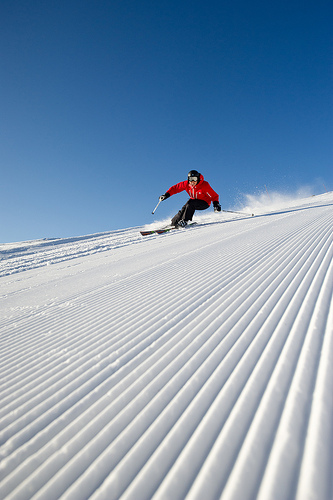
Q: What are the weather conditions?
A: It is cloudless.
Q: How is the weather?
A: It is cloudless.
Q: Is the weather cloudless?
A: Yes, it is cloudless.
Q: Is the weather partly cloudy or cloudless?
A: It is cloudless.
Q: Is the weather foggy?
A: No, it is cloudless.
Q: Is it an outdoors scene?
A: Yes, it is outdoors.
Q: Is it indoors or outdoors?
A: It is outdoors.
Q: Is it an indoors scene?
A: No, it is outdoors.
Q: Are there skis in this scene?
A: Yes, there are skis.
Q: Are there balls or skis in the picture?
A: Yes, there are skis.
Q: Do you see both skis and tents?
A: No, there are skis but no tents.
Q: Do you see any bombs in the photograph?
A: No, there are no bombs.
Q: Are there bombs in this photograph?
A: No, there are no bombs.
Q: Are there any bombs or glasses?
A: No, there are no bombs or glasses.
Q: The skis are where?
A: The skis are on the snow.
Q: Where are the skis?
A: The skis are on the snow.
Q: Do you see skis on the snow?
A: Yes, there are skis on the snow.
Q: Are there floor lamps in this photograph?
A: No, there are no floor lamps.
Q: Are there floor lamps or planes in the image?
A: No, there are no floor lamps or planes.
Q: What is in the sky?
A: The clouds are in the sky.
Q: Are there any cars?
A: No, there are no cars.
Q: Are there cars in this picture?
A: No, there are no cars.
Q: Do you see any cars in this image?
A: No, there are no cars.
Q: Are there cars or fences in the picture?
A: No, there are no cars or fences.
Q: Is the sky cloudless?
A: Yes, the sky is cloudless.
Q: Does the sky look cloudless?
A: Yes, the sky is cloudless.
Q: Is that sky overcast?
A: No, the sky is cloudless.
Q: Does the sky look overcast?
A: No, the sky is cloudless.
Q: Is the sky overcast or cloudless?
A: The sky is cloudless.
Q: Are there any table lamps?
A: No, there are no table lamps.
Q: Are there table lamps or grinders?
A: No, there are no table lamps or grinders.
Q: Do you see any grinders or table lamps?
A: No, there are no table lamps or grinders.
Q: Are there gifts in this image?
A: No, there are no gifts.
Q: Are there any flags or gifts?
A: No, there are no gifts or flags.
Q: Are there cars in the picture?
A: No, there are no cars.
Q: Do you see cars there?
A: No, there are no cars.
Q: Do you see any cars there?
A: No, there are no cars.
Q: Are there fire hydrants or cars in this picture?
A: No, there are no cars or fire hydrants.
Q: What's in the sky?
A: The clouds are in the sky.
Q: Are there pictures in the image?
A: No, there are no pictures.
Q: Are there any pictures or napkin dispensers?
A: No, there are no pictures or napkin dispensers.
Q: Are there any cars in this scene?
A: No, there are no cars.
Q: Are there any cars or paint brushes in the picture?
A: No, there are no cars or paint brushes.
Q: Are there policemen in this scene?
A: No, there are no policemen.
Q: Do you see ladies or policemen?
A: No, there are no policemen or ladies.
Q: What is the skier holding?
A: The skier is holding the pole.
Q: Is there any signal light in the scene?
A: No, there are no traffic lights.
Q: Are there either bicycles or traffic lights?
A: No, there are no traffic lights or bicycles.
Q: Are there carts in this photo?
A: No, there are no carts.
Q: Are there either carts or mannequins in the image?
A: No, there are no carts or mannequins.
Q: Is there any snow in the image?
A: Yes, there is snow.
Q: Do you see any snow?
A: Yes, there is snow.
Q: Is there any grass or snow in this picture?
A: Yes, there is snow.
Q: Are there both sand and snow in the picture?
A: No, there is snow but no sand.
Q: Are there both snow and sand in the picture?
A: No, there is snow but no sand.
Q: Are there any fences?
A: No, there are no fences.